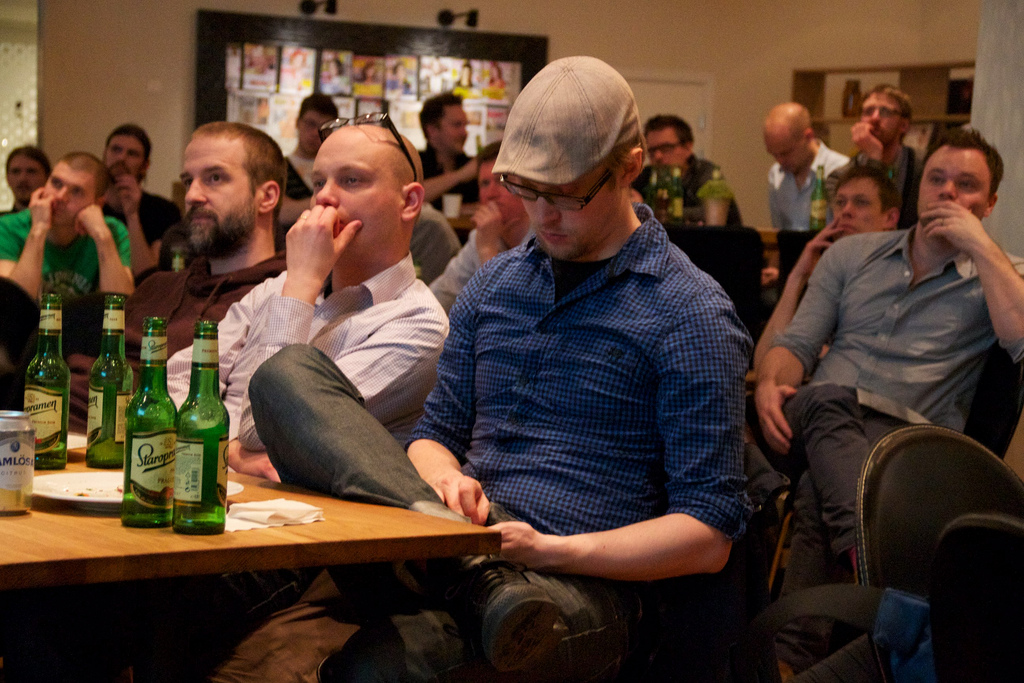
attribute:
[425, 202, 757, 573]
shirt — black, blue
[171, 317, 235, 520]
beer bottle — green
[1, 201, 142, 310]
shirt — green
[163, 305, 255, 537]
beerbottle — green and glass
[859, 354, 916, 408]
ground — empty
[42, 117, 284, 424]
person — sitting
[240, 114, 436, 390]
person — sitting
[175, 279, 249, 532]
beer bottle — green and glass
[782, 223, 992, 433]
shirt — gray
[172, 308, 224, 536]
bottle — empty, beer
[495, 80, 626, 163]
hat — brown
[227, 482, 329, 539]
napkin — white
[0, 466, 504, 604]
table — wooden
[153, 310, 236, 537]
bottle — beer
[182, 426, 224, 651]
beer bottle — green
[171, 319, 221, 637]
beer bottle — green